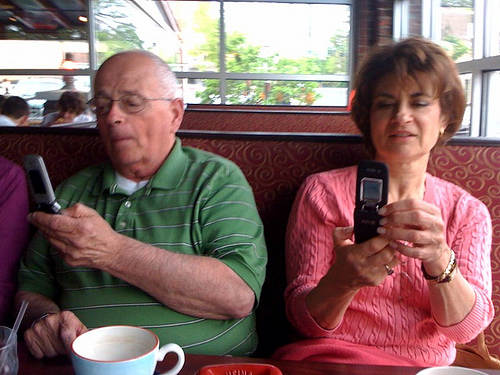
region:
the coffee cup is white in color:
[68, 327, 208, 367]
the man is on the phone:
[15, 158, 70, 213]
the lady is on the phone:
[346, 161, 389, 224]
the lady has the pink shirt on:
[304, 184, 394, 336]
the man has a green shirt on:
[174, 182, 241, 254]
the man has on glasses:
[89, 96, 154, 115]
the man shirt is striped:
[163, 206, 253, 252]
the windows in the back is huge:
[232, 40, 329, 93]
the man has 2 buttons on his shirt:
[117, 204, 137, 233]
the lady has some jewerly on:
[428, 269, 470, 286]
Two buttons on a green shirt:
[110, 191, 140, 232]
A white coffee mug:
[65, 316, 186, 371]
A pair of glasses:
[80, 82, 177, 117]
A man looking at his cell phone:
[10, 40, 260, 270]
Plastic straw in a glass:
[0, 295, 36, 372]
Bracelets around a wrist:
[411, 245, 461, 290]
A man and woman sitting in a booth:
[1, 26, 496, 368]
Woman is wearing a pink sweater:
[278, 32, 494, 367]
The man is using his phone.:
[26, 154, 99, 265]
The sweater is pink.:
[362, 295, 414, 352]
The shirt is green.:
[158, 183, 228, 238]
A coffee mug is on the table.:
[73, 323, 185, 373]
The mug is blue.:
[87, 362, 151, 374]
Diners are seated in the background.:
[0, 89, 88, 124]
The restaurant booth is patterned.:
[243, 141, 307, 171]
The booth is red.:
[243, 142, 316, 170]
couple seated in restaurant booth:
[4, 35, 496, 370]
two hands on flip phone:
[333, 158, 444, 289]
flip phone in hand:
[25, 153, 99, 268]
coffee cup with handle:
[71, 323, 183, 373]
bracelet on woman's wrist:
[387, 200, 462, 285]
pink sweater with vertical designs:
[289, 165, 493, 348]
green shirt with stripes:
[15, 137, 269, 353]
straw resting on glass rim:
[2, 297, 29, 373]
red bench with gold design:
[0, 140, 497, 356]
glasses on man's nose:
[87, 93, 174, 117]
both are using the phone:
[2, 41, 492, 371]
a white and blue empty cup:
[69, 325, 182, 373]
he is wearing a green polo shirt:
[25, 148, 263, 353]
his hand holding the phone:
[24, 155, 114, 265]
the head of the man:
[91, 55, 183, 170]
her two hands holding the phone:
[326, 165, 443, 286]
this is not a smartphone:
[354, 163, 388, 241]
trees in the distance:
[220, 36, 345, 78]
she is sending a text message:
[292, 41, 492, 370]